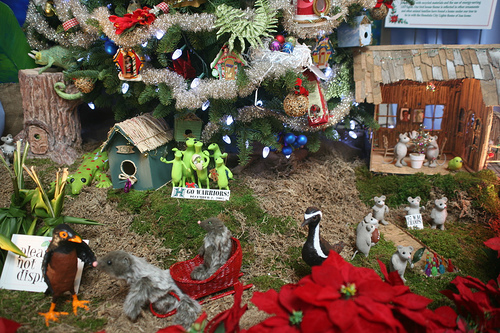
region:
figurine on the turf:
[369, 197, 391, 222]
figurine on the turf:
[399, 195, 431, 231]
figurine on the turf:
[427, 195, 457, 232]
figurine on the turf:
[297, 198, 324, 263]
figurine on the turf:
[383, 245, 413, 278]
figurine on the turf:
[39, 225, 91, 317]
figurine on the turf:
[202, 155, 239, 196]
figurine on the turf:
[163, 152, 178, 184]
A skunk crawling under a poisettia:
[271, 196, 327, 263]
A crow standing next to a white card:
[4, 218, 99, 324]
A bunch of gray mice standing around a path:
[360, 184, 465, 290]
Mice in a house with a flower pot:
[383, 106, 445, 173]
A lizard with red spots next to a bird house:
[70, 138, 114, 205]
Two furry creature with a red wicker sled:
[104, 207, 243, 320]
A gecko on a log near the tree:
[28, 39, 95, 99]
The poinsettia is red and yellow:
[281, 263, 376, 331]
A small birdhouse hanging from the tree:
[333, 12, 380, 49]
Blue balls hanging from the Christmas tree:
[268, 117, 311, 154]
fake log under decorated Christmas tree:
[16, 0, 389, 170]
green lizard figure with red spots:
[48, 146, 110, 194]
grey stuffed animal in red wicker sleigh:
[167, 212, 254, 302]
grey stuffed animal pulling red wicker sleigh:
[99, 223, 251, 321]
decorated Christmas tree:
[26, 2, 386, 176]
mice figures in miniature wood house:
[353, 41, 498, 176]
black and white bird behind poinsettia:
[248, 203, 463, 332]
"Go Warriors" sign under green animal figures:
[160, 133, 239, 203]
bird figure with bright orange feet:
[38, 224, 96, 326]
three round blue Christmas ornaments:
[281, 128, 308, 157]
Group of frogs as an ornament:
[152, 131, 277, 220]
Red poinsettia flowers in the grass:
[288, 263, 422, 331]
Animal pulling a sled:
[96, 214, 241, 331]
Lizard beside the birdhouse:
[56, 130, 111, 204]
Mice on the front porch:
[395, 120, 468, 180]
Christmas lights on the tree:
[144, 10, 234, 121]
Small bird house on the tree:
[344, 15, 374, 51]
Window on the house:
[422, 88, 446, 138]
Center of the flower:
[335, 278, 363, 305]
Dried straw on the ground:
[322, 163, 366, 235]